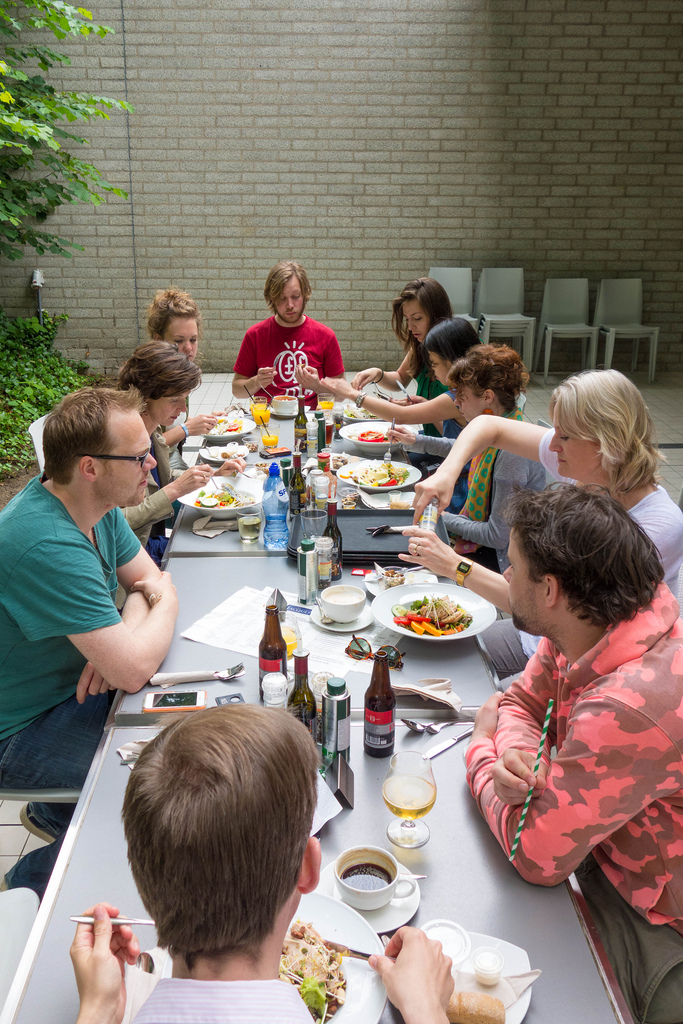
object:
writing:
[271, 340, 316, 401]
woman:
[396, 365, 682, 704]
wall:
[1, 58, 680, 381]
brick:
[400, 228, 438, 240]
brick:
[327, 183, 365, 197]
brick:
[401, 161, 441, 175]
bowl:
[320, 583, 368, 625]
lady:
[350, 274, 455, 473]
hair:
[389, 276, 454, 380]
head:
[498, 477, 665, 649]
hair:
[499, 482, 666, 631]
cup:
[333, 844, 417, 913]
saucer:
[310, 857, 422, 935]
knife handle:
[348, 948, 400, 965]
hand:
[364, 920, 458, 1020]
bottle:
[362, 649, 397, 759]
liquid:
[381, 774, 437, 823]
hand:
[489, 745, 550, 810]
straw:
[508, 696, 557, 867]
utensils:
[149, 661, 247, 688]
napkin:
[148, 669, 217, 691]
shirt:
[232, 313, 345, 413]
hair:
[263, 258, 313, 321]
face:
[102, 407, 158, 510]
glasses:
[62, 447, 151, 470]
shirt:
[0, 470, 143, 746]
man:
[232, 258, 350, 414]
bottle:
[321, 496, 344, 582]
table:
[0, 405, 629, 1024]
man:
[463, 476, 679, 1024]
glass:
[380, 746, 438, 851]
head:
[113, 699, 326, 984]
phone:
[141, 689, 208, 713]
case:
[141, 690, 208, 715]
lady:
[144, 285, 229, 533]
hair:
[146, 283, 205, 344]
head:
[146, 285, 202, 365]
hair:
[539, 361, 676, 496]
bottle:
[260, 460, 291, 554]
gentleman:
[0, 384, 181, 914]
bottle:
[287, 648, 318, 759]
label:
[363, 704, 396, 751]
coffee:
[339, 861, 395, 893]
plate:
[369, 579, 498, 644]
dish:
[391, 591, 473, 637]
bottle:
[287, 448, 307, 523]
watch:
[455, 557, 475, 590]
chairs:
[426, 265, 479, 336]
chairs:
[474, 265, 536, 372]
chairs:
[532, 274, 601, 386]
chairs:
[585, 274, 662, 382]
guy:
[66, 699, 457, 1023]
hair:
[118, 697, 322, 979]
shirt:
[112, 973, 324, 1024]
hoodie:
[463, 573, 683, 937]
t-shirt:
[517, 426, 682, 689]